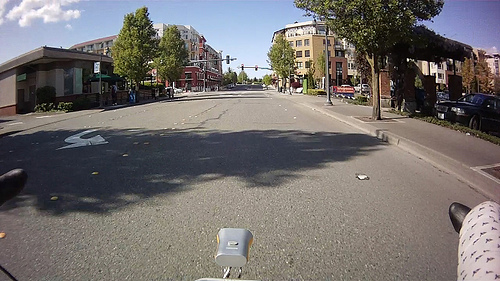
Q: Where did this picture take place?
A: It took place on the street.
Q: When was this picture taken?
A: It was taken in the day time.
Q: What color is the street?
A: The street is black.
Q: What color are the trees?
A: The trees are green.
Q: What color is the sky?
A: The sky is blue.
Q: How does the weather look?
A: It looks nice and sunny.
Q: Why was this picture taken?
A: To show the street.